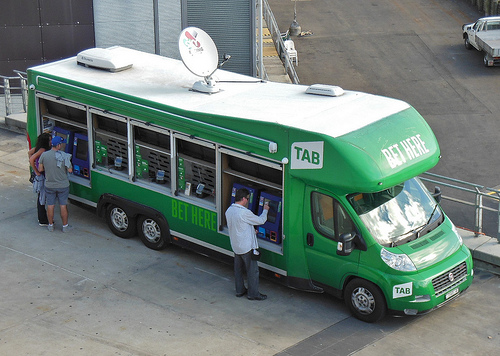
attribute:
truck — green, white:
[22, 41, 478, 320]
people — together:
[29, 129, 76, 234]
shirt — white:
[224, 204, 266, 256]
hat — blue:
[50, 136, 64, 146]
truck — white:
[457, 11, 499, 65]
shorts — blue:
[42, 184, 73, 206]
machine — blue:
[71, 132, 91, 180]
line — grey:
[271, 319, 403, 354]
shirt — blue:
[31, 174, 48, 206]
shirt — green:
[40, 150, 75, 190]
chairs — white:
[282, 38, 305, 65]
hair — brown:
[37, 131, 53, 148]